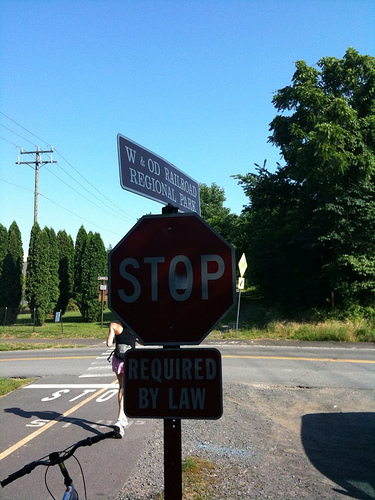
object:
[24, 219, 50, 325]
tree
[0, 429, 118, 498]
bike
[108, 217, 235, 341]
sign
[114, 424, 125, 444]
shoe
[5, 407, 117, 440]
shadow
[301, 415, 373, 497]
shadow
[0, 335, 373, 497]
road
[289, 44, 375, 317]
trees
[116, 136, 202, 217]
rectangular sign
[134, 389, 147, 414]
writing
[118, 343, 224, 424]
sign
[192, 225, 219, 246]
metal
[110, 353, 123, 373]
shorts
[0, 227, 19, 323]
trees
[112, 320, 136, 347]
tank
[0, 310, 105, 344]
corner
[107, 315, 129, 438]
girl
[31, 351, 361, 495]
ground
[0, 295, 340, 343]
yard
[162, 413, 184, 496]
post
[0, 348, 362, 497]
ground